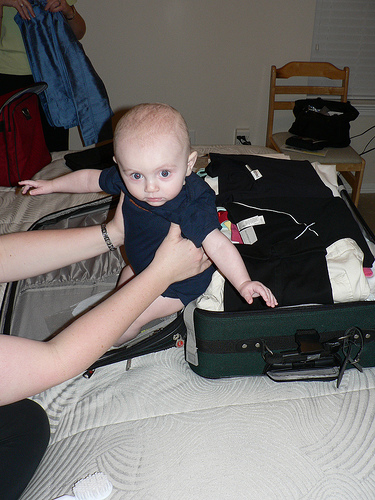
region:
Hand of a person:
[183, 206, 297, 321]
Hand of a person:
[15, 223, 219, 399]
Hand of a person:
[2, 194, 132, 274]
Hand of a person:
[15, 163, 117, 212]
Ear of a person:
[187, 143, 200, 185]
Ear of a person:
[109, 153, 117, 173]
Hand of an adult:
[18, 223, 213, 375]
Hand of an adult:
[2, 186, 150, 287]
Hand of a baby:
[178, 203, 284, 341]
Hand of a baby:
[17, 160, 115, 211]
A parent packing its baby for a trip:
[46, 105, 374, 471]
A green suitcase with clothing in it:
[186, 142, 363, 373]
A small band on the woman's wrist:
[96, 217, 121, 253]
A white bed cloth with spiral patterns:
[123, 385, 355, 483]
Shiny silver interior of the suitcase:
[11, 205, 182, 353]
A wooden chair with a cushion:
[265, 90, 372, 195]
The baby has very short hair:
[106, 100, 186, 155]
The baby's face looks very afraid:
[112, 139, 197, 211]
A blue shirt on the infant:
[104, 170, 217, 294]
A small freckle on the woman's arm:
[98, 341, 104, 353]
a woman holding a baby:
[0, 103, 279, 394]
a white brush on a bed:
[44, 472, 114, 498]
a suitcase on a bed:
[0, 173, 372, 376]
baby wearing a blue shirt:
[99, 165, 222, 302]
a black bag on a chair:
[287, 96, 358, 150]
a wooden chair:
[265, 57, 368, 207]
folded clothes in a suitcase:
[196, 153, 373, 312]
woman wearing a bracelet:
[97, 221, 114, 250]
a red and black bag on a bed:
[2, 80, 51, 188]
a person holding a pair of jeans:
[1, 1, 113, 146]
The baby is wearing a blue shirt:
[88, 100, 236, 326]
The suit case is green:
[6, 165, 366, 384]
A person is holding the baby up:
[4, 103, 274, 408]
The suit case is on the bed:
[12, 153, 364, 398]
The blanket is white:
[2, 191, 370, 488]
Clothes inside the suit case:
[197, 150, 366, 321]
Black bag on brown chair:
[285, 85, 354, 147]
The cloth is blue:
[8, 4, 115, 136]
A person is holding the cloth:
[2, 3, 107, 143]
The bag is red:
[0, 85, 55, 184]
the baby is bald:
[105, 95, 201, 204]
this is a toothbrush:
[47, 457, 118, 498]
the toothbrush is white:
[43, 463, 117, 499]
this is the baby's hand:
[235, 272, 275, 318]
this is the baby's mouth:
[142, 191, 164, 209]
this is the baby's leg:
[112, 272, 203, 352]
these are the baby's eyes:
[121, 163, 174, 186]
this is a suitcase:
[7, 152, 374, 385]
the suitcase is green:
[11, 148, 373, 383]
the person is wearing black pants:
[1, 389, 57, 498]